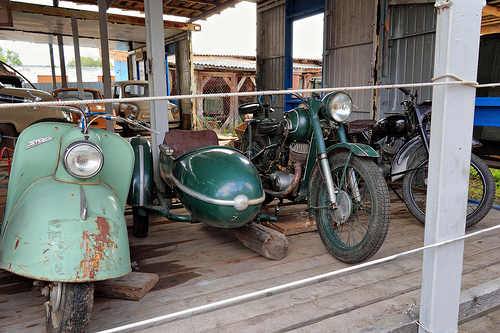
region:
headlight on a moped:
[62, 140, 102, 181]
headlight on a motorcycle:
[325, 92, 353, 124]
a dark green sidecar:
[159, 123, 264, 229]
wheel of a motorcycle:
[309, 151, 392, 267]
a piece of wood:
[231, 222, 284, 257]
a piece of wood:
[97, 270, 155, 300]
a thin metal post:
[417, 1, 482, 331]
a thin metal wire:
[0, 80, 481, 109]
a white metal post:
[142, 0, 171, 201]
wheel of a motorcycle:
[402, 143, 495, 230]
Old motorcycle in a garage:
[151, 55, 401, 277]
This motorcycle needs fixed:
[136, 66, 401, 271]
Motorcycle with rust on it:
[3, 80, 143, 330]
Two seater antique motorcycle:
[131, 113, 399, 261]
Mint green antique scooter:
[4, 88, 153, 331]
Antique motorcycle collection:
[1, 43, 493, 325]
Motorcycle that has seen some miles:
[131, 65, 396, 277]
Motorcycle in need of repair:
[11, 77, 141, 330]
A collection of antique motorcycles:
[31, 88, 396, 273]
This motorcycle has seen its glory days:
[131, 65, 401, 305]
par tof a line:
[259, 278, 284, 296]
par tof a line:
[258, 251, 293, 295]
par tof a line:
[408, 271, 419, 305]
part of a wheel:
[360, 149, 408, 172]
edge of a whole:
[413, 275, 440, 319]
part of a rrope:
[270, 245, 322, 307]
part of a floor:
[323, 282, 330, 293]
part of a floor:
[318, 281, 344, 312]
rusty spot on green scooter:
[67, 214, 118, 277]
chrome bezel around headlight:
[60, 138, 107, 181]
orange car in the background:
[47, 85, 117, 130]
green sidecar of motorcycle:
[129, 127, 281, 229]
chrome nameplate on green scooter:
[22, 132, 54, 152]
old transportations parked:
[1, 65, 498, 329]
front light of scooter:
[58, 136, 106, 181]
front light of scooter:
[321, 90, 355, 125]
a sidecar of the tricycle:
[124, 120, 270, 239]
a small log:
[228, 222, 290, 260]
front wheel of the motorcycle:
[311, 145, 396, 269]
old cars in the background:
[2, 75, 184, 126]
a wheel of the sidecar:
[124, 132, 159, 239]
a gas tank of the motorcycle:
[277, 104, 312, 143]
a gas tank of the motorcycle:
[370, 110, 412, 142]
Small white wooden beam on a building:
[425, 5, 470, 316]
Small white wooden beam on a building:
[136, 2, 174, 189]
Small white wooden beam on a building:
[88, 5, 125, 127]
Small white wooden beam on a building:
[63, 13, 95, 102]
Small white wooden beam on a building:
[49, 34, 70, 93]